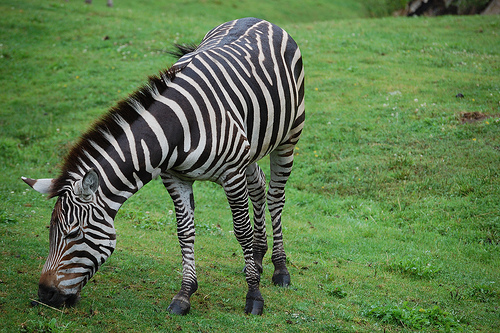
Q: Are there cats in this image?
A: No, there are no cats.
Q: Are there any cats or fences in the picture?
A: No, there are no cats or fences.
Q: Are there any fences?
A: No, there are no fences.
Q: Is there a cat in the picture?
A: No, there are no cats.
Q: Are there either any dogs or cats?
A: No, there are no cats or dogs.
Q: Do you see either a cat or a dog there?
A: No, there are no cats or dogs.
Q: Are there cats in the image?
A: No, there are no cats.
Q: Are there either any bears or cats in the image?
A: No, there are no cats or bears.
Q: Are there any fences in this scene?
A: No, there are no fences.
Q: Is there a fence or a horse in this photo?
A: No, there are no fences or horses.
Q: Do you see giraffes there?
A: No, there are no giraffes.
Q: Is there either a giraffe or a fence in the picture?
A: No, there are no giraffes or fences.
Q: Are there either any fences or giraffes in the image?
A: No, there are no giraffes or fences.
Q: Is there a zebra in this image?
A: Yes, there is a zebra.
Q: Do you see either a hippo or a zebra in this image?
A: Yes, there is a zebra.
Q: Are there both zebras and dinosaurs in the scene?
A: No, there is a zebra but no dinosaurs.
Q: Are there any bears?
A: No, there are no bears.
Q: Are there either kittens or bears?
A: No, there are no bears or kittens.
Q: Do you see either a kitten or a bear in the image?
A: No, there are no bears or kittens.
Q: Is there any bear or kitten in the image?
A: No, there are no bears or kittens.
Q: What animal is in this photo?
A: The animal is a zebra.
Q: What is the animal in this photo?
A: The animal is a zebra.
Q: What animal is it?
A: The animal is a zebra.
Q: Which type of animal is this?
A: This is a zebra.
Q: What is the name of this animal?
A: This is a zebra.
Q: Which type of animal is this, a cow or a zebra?
A: This is a zebra.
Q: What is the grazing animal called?
A: The animal is a zebra.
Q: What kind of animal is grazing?
A: The animal is a zebra.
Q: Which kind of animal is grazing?
A: The animal is a zebra.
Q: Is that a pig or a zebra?
A: That is a zebra.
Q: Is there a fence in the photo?
A: No, there are no fences.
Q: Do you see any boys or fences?
A: No, there are no fences or boys.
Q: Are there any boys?
A: No, there are no boys.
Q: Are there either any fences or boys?
A: No, there are no boys or fences.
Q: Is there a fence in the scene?
A: No, there are no fences.